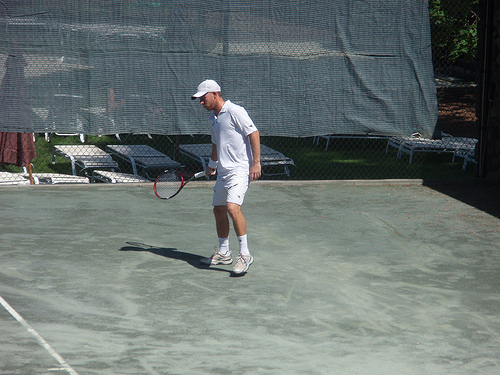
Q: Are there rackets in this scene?
A: Yes, there is a racket.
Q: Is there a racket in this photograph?
A: Yes, there is a racket.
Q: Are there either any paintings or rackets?
A: Yes, there is a racket.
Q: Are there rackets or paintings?
A: Yes, there is a racket.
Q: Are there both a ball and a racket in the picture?
A: No, there is a racket but no balls.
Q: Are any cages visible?
A: No, there are no cages.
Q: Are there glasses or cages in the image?
A: No, there are no cages or glasses.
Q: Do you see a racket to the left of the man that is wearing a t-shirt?
A: Yes, there is a racket to the left of the man.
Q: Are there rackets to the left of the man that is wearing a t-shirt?
A: Yes, there is a racket to the left of the man.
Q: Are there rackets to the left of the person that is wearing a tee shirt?
A: Yes, there is a racket to the left of the man.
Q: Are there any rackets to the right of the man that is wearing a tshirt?
A: No, the racket is to the left of the man.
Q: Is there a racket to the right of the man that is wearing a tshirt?
A: No, the racket is to the left of the man.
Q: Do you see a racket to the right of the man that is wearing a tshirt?
A: No, the racket is to the left of the man.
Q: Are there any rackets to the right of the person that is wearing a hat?
A: No, the racket is to the left of the man.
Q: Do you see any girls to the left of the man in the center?
A: No, there is a racket to the left of the man.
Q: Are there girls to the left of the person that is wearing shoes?
A: No, there is a racket to the left of the man.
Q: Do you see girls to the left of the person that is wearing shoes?
A: No, there is a racket to the left of the man.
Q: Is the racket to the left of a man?
A: Yes, the racket is to the left of a man.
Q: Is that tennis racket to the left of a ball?
A: No, the tennis racket is to the left of a man.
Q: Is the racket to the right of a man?
A: No, the racket is to the left of a man.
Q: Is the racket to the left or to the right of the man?
A: The racket is to the left of the man.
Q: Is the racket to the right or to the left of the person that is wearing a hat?
A: The racket is to the left of the man.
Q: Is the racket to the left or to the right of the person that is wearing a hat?
A: The racket is to the left of the man.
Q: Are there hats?
A: Yes, there is a hat.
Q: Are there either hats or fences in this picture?
A: Yes, there is a hat.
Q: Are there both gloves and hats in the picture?
A: No, there is a hat but no gloves.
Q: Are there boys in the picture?
A: No, there are no boys.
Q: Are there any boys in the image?
A: No, there are no boys.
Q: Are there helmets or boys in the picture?
A: No, there are no boys or helmets.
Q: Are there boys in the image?
A: No, there are no boys.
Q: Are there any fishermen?
A: No, there are no fishermen.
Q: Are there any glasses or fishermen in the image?
A: No, there are no fishermen or glasses.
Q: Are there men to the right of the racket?
A: Yes, there is a man to the right of the racket.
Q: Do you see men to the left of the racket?
A: No, the man is to the right of the racket.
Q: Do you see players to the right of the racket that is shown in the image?
A: No, there is a man to the right of the racket.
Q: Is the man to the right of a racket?
A: Yes, the man is to the right of a racket.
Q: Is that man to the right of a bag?
A: No, the man is to the right of a racket.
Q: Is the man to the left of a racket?
A: No, the man is to the right of a racket.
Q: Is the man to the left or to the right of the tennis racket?
A: The man is to the right of the tennis racket.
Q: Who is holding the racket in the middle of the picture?
A: The man is holding the racket.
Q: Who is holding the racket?
A: The man is holding the racket.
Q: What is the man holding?
A: The man is holding the tennis racket.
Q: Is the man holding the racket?
A: Yes, the man is holding the racket.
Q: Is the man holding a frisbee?
A: No, the man is holding the racket.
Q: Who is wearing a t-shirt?
A: The man is wearing a t-shirt.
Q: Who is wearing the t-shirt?
A: The man is wearing a t-shirt.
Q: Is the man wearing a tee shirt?
A: Yes, the man is wearing a tee shirt.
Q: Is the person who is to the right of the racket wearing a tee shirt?
A: Yes, the man is wearing a tee shirt.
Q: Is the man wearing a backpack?
A: No, the man is wearing a tee shirt.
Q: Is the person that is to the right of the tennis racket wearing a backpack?
A: No, the man is wearing a tee shirt.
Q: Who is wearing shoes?
A: The man is wearing shoes.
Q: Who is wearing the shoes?
A: The man is wearing shoes.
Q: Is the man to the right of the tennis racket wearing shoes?
A: Yes, the man is wearing shoes.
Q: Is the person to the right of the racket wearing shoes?
A: Yes, the man is wearing shoes.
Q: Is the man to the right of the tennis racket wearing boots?
A: No, the man is wearing shoes.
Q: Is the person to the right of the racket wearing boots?
A: No, the man is wearing shoes.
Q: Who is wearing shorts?
A: The man is wearing shorts.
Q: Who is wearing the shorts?
A: The man is wearing shorts.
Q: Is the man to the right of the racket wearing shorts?
A: Yes, the man is wearing shorts.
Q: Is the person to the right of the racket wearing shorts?
A: Yes, the man is wearing shorts.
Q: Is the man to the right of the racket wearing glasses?
A: No, the man is wearing shorts.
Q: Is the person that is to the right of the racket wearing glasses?
A: No, the man is wearing shorts.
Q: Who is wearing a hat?
A: The man is wearing a hat.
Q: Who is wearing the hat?
A: The man is wearing a hat.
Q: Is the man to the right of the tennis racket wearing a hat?
A: Yes, the man is wearing a hat.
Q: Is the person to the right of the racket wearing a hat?
A: Yes, the man is wearing a hat.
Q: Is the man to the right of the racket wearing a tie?
A: No, the man is wearing a hat.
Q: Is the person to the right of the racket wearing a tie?
A: No, the man is wearing a hat.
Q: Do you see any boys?
A: No, there are no boys.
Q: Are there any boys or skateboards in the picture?
A: No, there are no boys or skateboards.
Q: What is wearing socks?
A: The shoes are wearing socks.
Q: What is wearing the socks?
A: The shoes are wearing socks.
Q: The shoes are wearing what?
A: The shoes are wearing socks.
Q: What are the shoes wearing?
A: The shoes are wearing socks.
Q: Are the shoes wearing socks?
A: Yes, the shoes are wearing socks.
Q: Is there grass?
A: Yes, there is grass.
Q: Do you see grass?
A: Yes, there is grass.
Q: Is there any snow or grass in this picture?
A: Yes, there is grass.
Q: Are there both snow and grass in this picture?
A: No, there is grass but no snow.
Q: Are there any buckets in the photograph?
A: No, there are no buckets.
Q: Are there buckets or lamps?
A: No, there are no buckets or lamps.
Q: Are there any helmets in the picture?
A: No, there are no helmets.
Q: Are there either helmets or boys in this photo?
A: No, there are no helmets or boys.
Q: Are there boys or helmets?
A: No, there are no helmets or boys.